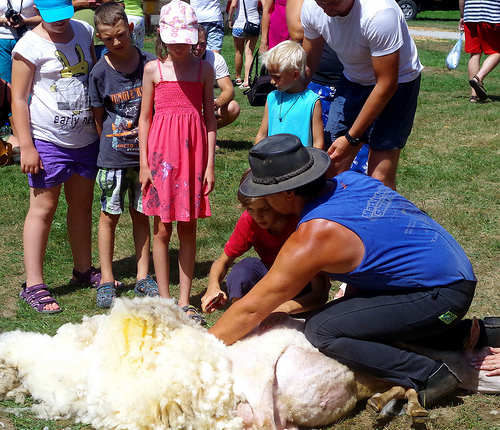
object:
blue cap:
[32, 0, 77, 24]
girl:
[11, 0, 124, 314]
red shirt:
[224, 209, 332, 292]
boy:
[201, 167, 332, 330]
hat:
[239, 133, 331, 197]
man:
[207, 133, 500, 411]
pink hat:
[158, 0, 198, 44]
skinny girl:
[138, 0, 218, 326]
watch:
[345, 130, 362, 147]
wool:
[0, 295, 361, 430]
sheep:
[0, 296, 430, 429]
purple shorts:
[27, 137, 101, 188]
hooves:
[367, 385, 430, 423]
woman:
[226, 0, 267, 89]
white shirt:
[233, 0, 263, 30]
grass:
[443, 94, 474, 141]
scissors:
[205, 292, 224, 311]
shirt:
[11, 18, 101, 149]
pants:
[303, 278, 484, 403]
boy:
[256, 40, 324, 150]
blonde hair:
[258, 40, 308, 82]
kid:
[88, 0, 164, 309]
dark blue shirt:
[88, 45, 163, 168]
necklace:
[279, 82, 308, 122]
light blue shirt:
[267, 88, 321, 148]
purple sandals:
[19, 281, 63, 314]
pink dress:
[142, 58, 213, 224]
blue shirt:
[295, 170, 477, 292]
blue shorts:
[232, 22, 262, 38]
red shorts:
[464, 22, 500, 56]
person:
[457, 1, 500, 103]